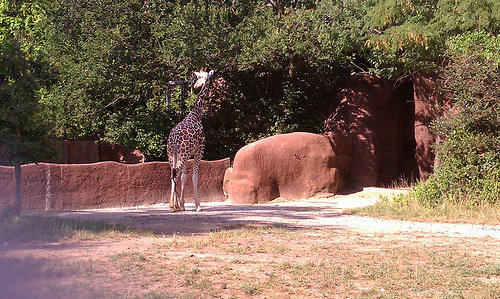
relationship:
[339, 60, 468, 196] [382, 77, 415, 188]
cave has an entrance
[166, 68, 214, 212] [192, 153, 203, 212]
giraffe has leg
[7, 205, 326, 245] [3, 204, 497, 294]
shadows on top of ground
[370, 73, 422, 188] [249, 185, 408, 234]
an entrance has pathway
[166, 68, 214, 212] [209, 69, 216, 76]
giraffe has ear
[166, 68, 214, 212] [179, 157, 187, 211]
giraffe has leg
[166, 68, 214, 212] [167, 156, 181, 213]
giraffe has leg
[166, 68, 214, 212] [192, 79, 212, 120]
giraffe has neck